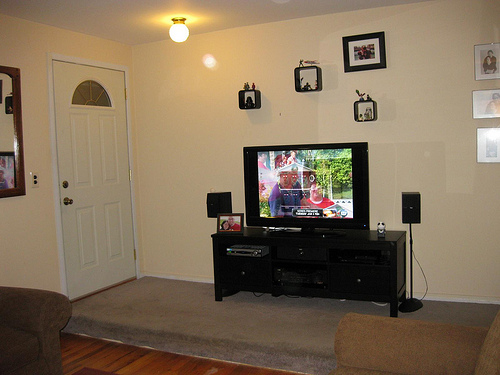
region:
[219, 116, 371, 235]
flat screen tv near wall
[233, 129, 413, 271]
tv has black frame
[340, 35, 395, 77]
picture frame on wall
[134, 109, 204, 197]
wall is off white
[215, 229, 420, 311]
black stand under tv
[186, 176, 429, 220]
black speakers beside tv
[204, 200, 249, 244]
picture frame on stand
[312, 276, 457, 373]
brown chair in front of tv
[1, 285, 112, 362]
dark brown chair near door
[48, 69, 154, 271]
white door beside tv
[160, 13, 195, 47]
a light on the ceiling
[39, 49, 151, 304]
a white door in a room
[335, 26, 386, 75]
a picture on a wall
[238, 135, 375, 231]
a flat TV is on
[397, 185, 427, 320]
a speaker stands on the floor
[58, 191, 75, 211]
a door handle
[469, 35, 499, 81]
a picture on the wall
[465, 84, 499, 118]
a picture on the wall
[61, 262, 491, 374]
a carpet in front the door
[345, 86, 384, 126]
a small shelf with ornaments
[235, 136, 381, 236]
TV on a stand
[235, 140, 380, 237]
TV is on a stand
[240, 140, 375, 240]
Black TV on a stand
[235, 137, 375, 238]
Black TV is on a stand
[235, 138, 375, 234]
Flat screen on a stand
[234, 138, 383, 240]
Flat screen is on a stand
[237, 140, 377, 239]
Black flat screen on a stand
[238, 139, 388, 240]
Black flat screen is on a stand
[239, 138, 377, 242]
Flat screen TV on a stand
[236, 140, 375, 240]
Flat screen TV is on a stand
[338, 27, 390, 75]
a black picture frame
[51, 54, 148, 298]
a white door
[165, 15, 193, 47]
a small ceiling light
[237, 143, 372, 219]
a large black t.v.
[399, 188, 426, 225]
a small black speaker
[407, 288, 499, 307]
white floor trim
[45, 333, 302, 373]
part of a hardwood floor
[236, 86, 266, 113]
a small black shelf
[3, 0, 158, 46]
part of a white ceiling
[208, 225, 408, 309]
a long black t.v. stand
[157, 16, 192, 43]
The light on the ceiling that is on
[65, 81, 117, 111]
The small window in the white door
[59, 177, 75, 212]
The lock and door knob on the white door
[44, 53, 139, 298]
A white door with a lock and a window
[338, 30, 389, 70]
A black picture frame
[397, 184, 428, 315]
A speaker on a stand next to the TV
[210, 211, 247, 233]
A picture frame next to the TV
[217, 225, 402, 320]
A black table with a TV on it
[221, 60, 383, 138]
Three black shelves on the wall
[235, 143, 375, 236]
A tv with something playing on it